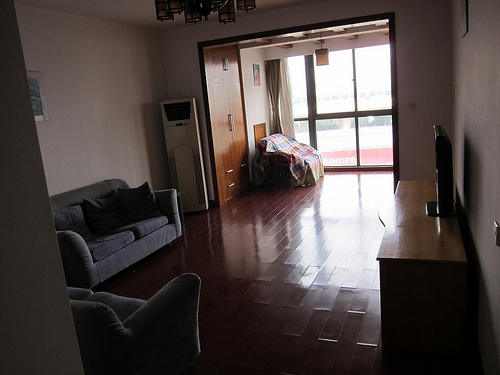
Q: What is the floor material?
A: Hardwood.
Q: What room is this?
A: Living room.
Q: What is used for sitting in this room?
A: Couch.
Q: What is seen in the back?
A: Windows.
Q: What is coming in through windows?
A: Light.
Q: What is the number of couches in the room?
A: Two.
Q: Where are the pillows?
A: On the couch.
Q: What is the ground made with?
A: Wood.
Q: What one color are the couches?
A: Grey.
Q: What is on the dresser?
A: A tv.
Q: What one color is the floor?
A: Brown.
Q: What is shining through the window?
A: Sunlight.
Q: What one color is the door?
A: Brown.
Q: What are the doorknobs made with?
A: Metal.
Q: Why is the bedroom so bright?
A: The window is open.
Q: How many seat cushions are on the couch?
A: 2.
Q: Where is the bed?
A: In the bedroom.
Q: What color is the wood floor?
A: Brown.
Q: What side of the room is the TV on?
A: The right side.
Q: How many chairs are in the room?
A: 1.